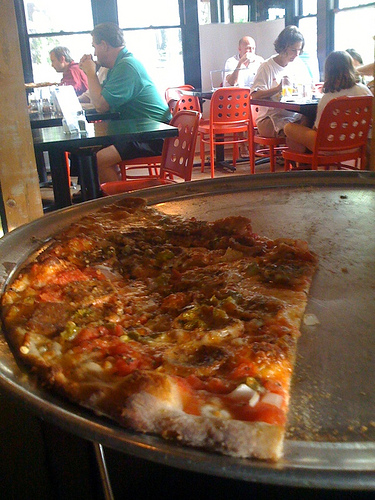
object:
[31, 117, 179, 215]
table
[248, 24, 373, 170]
people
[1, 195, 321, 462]
pizza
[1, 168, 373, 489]
pan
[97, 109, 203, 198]
chair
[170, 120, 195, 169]
pattern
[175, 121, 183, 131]
hole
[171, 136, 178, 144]
hole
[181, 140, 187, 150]
hole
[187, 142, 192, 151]
hole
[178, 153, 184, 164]
hole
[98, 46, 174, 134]
green shirt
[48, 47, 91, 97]
man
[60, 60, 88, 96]
red shirt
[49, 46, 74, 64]
hair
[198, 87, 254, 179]
chair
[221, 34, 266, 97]
man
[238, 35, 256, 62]
head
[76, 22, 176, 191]
man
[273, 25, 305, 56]
hair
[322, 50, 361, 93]
hair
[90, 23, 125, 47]
hair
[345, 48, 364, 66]
hair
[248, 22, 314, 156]
girl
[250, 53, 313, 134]
shirt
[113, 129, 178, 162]
shorts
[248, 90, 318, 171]
table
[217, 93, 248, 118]
circles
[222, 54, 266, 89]
shirt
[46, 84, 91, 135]
menu